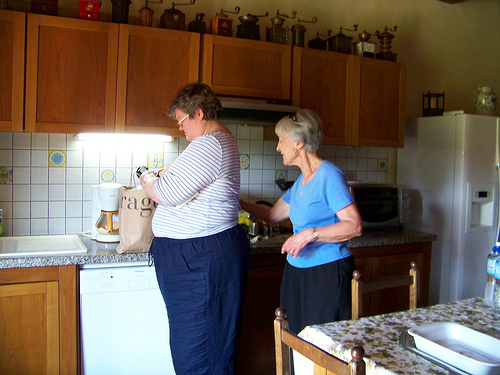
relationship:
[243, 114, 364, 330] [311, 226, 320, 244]
lady wears watch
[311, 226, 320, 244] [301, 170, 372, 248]
watch on arm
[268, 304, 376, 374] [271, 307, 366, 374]
chair has chair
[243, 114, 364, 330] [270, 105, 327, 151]
lady has blonde hair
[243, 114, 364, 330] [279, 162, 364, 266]
lady had shirt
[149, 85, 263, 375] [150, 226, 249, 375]
woman wears pants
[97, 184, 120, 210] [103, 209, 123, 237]
candle on stand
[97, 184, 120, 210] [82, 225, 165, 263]
candle on countertop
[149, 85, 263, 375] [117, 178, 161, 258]
woman has groceries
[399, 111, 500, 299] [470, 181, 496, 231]
refrigerator has icemaker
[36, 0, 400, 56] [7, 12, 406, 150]
rack on cabinets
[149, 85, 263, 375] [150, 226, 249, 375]
woman has pants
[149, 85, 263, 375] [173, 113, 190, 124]
woman wears eye glasses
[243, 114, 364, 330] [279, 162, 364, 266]
lady in shirt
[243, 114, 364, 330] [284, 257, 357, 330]
lady in pants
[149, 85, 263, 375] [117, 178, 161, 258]
woman with bag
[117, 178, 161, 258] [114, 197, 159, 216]
groceries has letters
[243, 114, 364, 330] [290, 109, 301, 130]
lady has sunglasses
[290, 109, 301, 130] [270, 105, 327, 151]
sunglasses on woman's head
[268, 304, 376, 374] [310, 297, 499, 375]
chair at table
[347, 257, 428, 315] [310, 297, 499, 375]
chair at table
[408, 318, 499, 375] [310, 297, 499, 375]
dish on table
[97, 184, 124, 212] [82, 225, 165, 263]
candle on countertop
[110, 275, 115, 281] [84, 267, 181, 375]
dot on dishwasher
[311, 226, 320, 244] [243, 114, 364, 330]
watch on lady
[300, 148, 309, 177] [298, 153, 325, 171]
vein in neck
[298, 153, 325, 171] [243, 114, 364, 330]
neck of lady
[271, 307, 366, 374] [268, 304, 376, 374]
chair on chair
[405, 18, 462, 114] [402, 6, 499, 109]
shadow on wall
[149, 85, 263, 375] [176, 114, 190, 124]
woman wears eye glasses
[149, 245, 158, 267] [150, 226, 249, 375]
string on pants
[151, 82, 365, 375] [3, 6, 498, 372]
friends in kitchen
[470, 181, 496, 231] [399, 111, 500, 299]
icemaker in refrigerator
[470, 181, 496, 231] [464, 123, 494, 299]
icemaker in door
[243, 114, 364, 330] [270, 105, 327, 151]
lady has hair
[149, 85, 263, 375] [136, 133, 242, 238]
woman has striped shirt